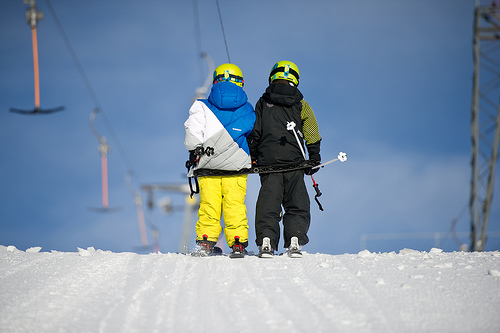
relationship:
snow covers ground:
[1, 235, 496, 330] [4, 243, 497, 320]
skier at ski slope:
[183, 62, 263, 261] [6, 248, 500, 325]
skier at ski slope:
[244, 57, 327, 259] [6, 248, 500, 325]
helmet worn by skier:
[210, 60, 245, 87] [183, 62, 263, 261]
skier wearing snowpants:
[183, 62, 263, 261] [198, 174, 252, 240]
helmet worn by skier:
[267, 62, 299, 84] [244, 57, 327, 259]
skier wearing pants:
[244, 57, 327, 259] [254, 171, 314, 240]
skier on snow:
[183, 62, 263, 261] [1, 235, 496, 330]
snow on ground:
[1, 235, 496, 330] [4, 243, 497, 320]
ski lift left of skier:
[3, 3, 232, 249] [183, 62, 263, 261]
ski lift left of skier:
[3, 3, 232, 249] [244, 57, 327, 247]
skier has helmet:
[183, 62, 263, 261] [210, 60, 245, 87]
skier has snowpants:
[183, 62, 263, 261] [198, 174, 252, 240]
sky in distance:
[6, 1, 499, 244] [17, 0, 495, 243]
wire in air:
[31, 0, 230, 203] [19, 0, 482, 333]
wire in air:
[214, 0, 246, 72] [19, 0, 482, 333]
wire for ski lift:
[31, 0, 230, 203] [3, 3, 232, 249]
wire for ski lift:
[214, 0, 246, 72] [3, 3, 232, 249]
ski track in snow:
[163, 253, 194, 326] [1, 235, 496, 330]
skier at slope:
[244, 57, 327, 259] [6, 248, 500, 325]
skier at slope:
[183, 62, 263, 261] [6, 248, 500, 325]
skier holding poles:
[244, 57, 327, 259] [285, 113, 352, 192]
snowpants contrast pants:
[198, 174, 252, 240] [254, 171, 314, 240]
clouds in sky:
[315, 145, 497, 232] [6, 1, 499, 244]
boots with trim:
[195, 237, 247, 253] [202, 233, 243, 247]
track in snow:
[87, 254, 148, 332] [1, 235, 496, 330]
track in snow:
[322, 250, 393, 332] [1, 235, 496, 330]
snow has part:
[1, 235, 496, 330] [428, 246, 441, 256]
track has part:
[87, 254, 148, 332] [116, 257, 144, 279]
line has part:
[187, 0, 211, 90] [187, 0, 212, 39]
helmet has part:
[210, 60, 245, 87] [215, 71, 244, 80]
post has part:
[466, 2, 499, 244] [481, 112, 500, 248]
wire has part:
[31, 0, 230, 203] [123, 173, 185, 197]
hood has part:
[204, 80, 249, 112] [223, 82, 239, 108]